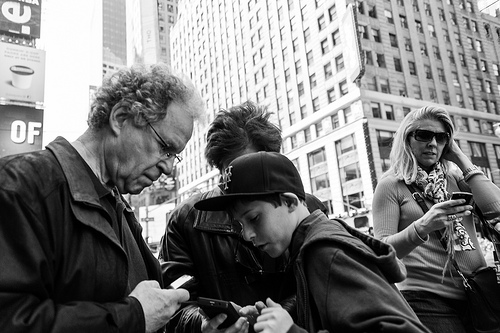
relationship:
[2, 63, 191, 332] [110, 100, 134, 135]
man has ear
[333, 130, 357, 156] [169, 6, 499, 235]
window on building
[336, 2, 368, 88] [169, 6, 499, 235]
sign on building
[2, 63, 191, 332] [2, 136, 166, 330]
man wearing jacket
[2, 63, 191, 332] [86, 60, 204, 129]
man has hair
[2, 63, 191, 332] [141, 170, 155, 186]
man has mouth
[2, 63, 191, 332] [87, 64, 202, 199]
man has head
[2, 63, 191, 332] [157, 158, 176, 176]
man has nose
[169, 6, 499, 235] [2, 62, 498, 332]
building behind people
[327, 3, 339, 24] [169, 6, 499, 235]
window on building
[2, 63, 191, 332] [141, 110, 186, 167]
man wearing glasses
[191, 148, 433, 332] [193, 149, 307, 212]
boy wearing baseball hat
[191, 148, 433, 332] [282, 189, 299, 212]
boy has ear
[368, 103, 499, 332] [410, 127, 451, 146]
people wearing sunglasses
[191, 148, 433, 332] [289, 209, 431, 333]
boy wearing sweatshirt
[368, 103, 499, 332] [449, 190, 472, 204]
people looking at cell phone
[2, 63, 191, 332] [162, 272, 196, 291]
man looking at phone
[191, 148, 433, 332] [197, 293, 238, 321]
boy looking at phone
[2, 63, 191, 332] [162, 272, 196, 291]
man holding phone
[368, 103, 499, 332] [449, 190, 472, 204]
people holding cell phone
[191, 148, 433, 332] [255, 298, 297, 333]
boy has hands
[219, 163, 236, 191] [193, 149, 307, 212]
logo on baseball hat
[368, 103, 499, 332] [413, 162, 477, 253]
people wearing scarf